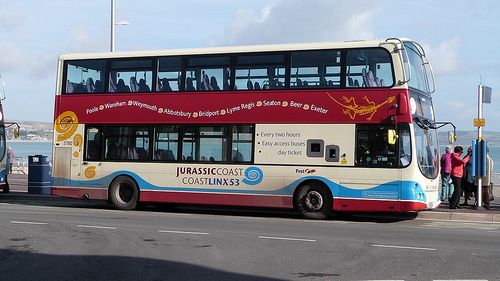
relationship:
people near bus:
[443, 142, 493, 211] [52, 37, 444, 222]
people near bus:
[443, 142, 493, 211] [0, 89, 14, 191]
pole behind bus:
[108, 0, 118, 55] [52, 37, 444, 222]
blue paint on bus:
[55, 168, 427, 200] [52, 37, 444, 222]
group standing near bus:
[435, 148, 499, 199] [52, 37, 444, 222]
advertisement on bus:
[175, 162, 266, 187] [34, 23, 498, 247]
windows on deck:
[84, 127, 253, 164] [53, 123, 429, 211]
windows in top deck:
[62, 48, 396, 90] [56, 38, 433, 114]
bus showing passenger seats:
[52, 37, 444, 222] [75, 69, 382, 86]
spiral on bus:
[46, 99, 103, 146] [52, 37, 444, 222]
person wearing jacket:
[442, 144, 451, 198] [439, 152, 454, 174]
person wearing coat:
[442, 144, 451, 198] [450, 151, 471, 178]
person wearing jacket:
[440, 144, 454, 202] [439, 152, 454, 174]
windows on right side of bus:
[84, 127, 253, 164] [52, 37, 444, 222]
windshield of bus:
[412, 117, 439, 180] [34, 53, 444, 225]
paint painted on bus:
[53, 110, 78, 146] [52, 37, 444, 222]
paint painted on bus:
[70, 133, 83, 149] [52, 37, 444, 222]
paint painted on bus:
[71, 150, 80, 158] [52, 37, 444, 222]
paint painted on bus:
[82, 164, 97, 179] [52, 37, 444, 222]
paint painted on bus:
[323, 88, 396, 123] [52, 37, 444, 222]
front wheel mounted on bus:
[292, 180, 337, 219] [52, 37, 444, 222]